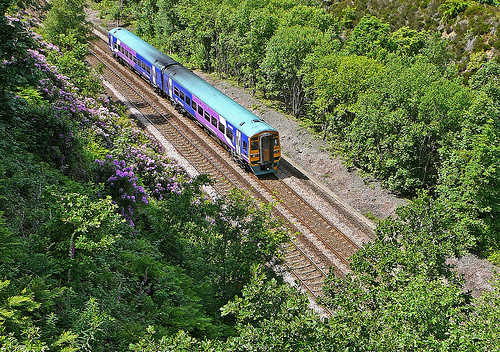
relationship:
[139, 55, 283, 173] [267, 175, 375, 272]
train on track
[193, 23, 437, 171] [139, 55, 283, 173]
wilderness by train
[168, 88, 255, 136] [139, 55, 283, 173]
glass on train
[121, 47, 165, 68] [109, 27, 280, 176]
windows on train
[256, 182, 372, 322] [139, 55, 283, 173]
tracks on train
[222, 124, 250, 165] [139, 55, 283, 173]
doors on train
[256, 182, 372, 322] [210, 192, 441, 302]
tracks on ground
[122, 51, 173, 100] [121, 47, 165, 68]
purple around windows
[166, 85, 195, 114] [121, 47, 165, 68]
blue around windows